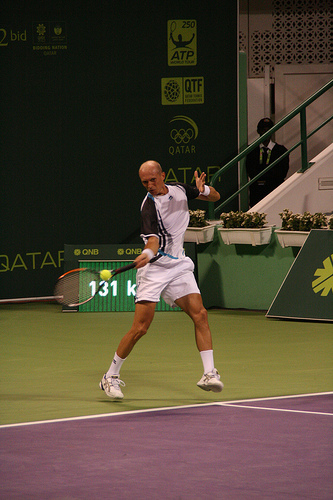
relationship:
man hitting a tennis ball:
[95, 157, 226, 404] [99, 267, 113, 282]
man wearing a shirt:
[95, 157, 226, 404] [133, 178, 199, 270]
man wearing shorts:
[95, 157, 226, 404] [133, 258, 203, 305]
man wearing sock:
[95, 157, 226, 404] [197, 347, 218, 379]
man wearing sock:
[95, 157, 226, 404] [106, 348, 129, 379]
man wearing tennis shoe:
[95, 157, 226, 404] [194, 369, 224, 395]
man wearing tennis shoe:
[95, 157, 226, 404] [97, 369, 125, 403]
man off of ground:
[95, 157, 226, 404] [2, 306, 332, 500]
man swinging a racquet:
[95, 157, 226, 404] [51, 253, 157, 311]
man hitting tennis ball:
[95, 157, 226, 404] [99, 267, 113, 282]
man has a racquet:
[95, 157, 226, 404] [51, 253, 157, 311]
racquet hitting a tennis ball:
[51, 253, 157, 311] [99, 267, 113, 282]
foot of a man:
[199, 377, 222, 390] [95, 157, 226, 404]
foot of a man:
[98, 380, 123, 401] [95, 157, 226, 404]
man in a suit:
[241, 115, 294, 213] [243, 140, 289, 206]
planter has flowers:
[181, 223, 215, 245] [185, 208, 208, 231]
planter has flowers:
[217, 225, 274, 248] [221, 210, 264, 227]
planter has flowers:
[272, 227, 310, 251] [280, 206, 333, 231]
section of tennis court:
[2, 295, 333, 439] [2, 297, 331, 498]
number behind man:
[86, 280, 118, 301] [95, 157, 226, 404]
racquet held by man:
[51, 253, 157, 311] [95, 157, 226, 404]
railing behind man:
[199, 75, 332, 214] [95, 157, 226, 404]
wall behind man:
[0, 1, 245, 306] [95, 157, 226, 404]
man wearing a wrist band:
[95, 157, 226, 404] [200, 182, 212, 198]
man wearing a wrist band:
[95, 157, 226, 404] [141, 249, 162, 267]